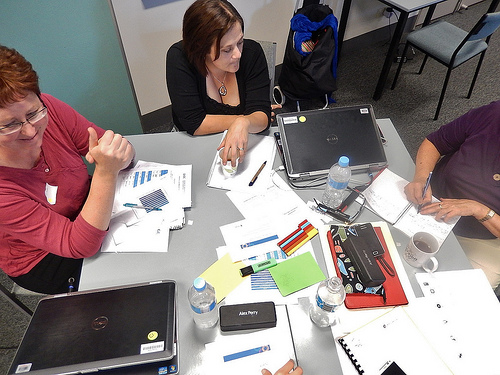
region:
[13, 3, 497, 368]
People working at the office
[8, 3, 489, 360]
Office meeting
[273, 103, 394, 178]
Laptop computer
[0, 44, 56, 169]
A Woman wearing the prescription glasses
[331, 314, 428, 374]
Spiral bound document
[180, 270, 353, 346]
Two water bottles on the desk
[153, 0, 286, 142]
A woman wearing a black t-shirt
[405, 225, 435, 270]
White mug on the table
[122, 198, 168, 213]
Pen over the papers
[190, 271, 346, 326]
Bottles of water on the table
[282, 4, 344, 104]
a blue and black backpack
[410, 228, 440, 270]
a cup with coffee in it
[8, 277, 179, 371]
a black 3 ring binder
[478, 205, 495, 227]
a ladies wristwatch on her left wrist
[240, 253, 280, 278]
a green highlighter with black cap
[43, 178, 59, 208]
a name tag on a red shirt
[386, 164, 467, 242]
a woman takes notes in a spiral notebook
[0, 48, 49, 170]
lady with red hair wears eyeglasses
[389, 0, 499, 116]
grey blue side chair with a black metal frame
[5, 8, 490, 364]
Three people at a table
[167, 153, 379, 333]
Three water bottles on the table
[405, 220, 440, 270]
A coffe mug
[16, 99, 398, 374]
There are two laptops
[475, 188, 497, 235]
She has a watch on her left wrist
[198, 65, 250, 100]
She is wearing a necklace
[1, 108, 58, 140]
She is wearing glasses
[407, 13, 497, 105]
An empty chair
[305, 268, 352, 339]
a plastic water bottle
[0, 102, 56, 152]
a woman wearing glasses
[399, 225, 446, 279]
a coffee cup on a table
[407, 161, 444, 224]
a person holding a pen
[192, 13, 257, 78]
a woman with short hair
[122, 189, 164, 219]
a ink pen on a table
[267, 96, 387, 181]
a laptop computer on a table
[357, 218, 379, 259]
a cell phone laying on a table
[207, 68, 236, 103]
a woman wearing a necklace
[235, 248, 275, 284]
a green sharpie pen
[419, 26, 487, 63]
a grey and blue chair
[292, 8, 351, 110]
a blue and black bookbag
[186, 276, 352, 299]
two warter bottles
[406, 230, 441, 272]
a white coffe cup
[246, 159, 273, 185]
a small and brown pen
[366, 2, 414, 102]
a black handle on a chair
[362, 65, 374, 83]
a black white and grey floor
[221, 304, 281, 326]
eye glass case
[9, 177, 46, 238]
a pink shirt